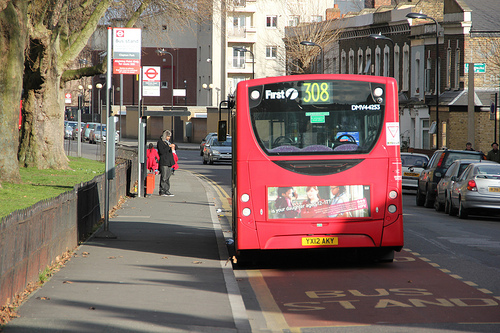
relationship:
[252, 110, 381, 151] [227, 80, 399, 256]
windshield on bus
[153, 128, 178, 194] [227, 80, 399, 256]
man standing next to bus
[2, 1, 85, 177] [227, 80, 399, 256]
tree next to bus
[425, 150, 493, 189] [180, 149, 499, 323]
car parked on street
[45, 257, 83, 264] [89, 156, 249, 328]
leaves on sidewalk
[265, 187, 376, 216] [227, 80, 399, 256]
banner on bus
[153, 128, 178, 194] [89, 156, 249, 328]
person standing on sidewalk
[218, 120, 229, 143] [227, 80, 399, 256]
rear view mirror on bus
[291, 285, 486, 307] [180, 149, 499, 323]
painting on road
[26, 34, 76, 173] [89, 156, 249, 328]
large tree trunk next to sidewalk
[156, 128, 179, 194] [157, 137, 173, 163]
man wearing coat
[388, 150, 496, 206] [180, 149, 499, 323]
cars parked along street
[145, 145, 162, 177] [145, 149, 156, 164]
woman wearing red jacket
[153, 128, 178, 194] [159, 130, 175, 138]
man wearing hat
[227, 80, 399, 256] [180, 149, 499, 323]
bus on road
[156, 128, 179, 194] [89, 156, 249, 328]
man standing on sidewalk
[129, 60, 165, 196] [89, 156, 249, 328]
bus stop on sidewalk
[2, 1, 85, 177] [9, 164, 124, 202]
tree on grass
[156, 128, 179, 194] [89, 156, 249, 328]
man on sidewalk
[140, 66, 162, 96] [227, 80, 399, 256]
sign next to bus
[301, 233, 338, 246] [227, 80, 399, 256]
license plate on bus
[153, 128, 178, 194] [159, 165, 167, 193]
man wearing jeans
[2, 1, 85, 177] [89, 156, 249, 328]
tree next to sidewalk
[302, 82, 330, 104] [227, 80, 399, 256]
number on bus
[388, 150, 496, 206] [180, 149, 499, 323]
cars on street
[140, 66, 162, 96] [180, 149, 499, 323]
sign on road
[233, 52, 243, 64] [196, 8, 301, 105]
windows on building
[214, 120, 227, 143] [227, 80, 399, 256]
rear view mirror on bus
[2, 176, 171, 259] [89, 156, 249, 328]
wall next to sidewalk